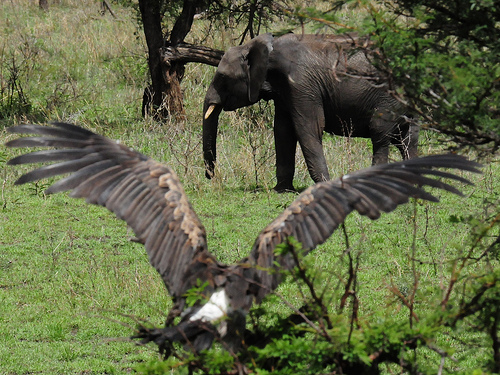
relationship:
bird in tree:
[8, 121, 485, 358] [129, 212, 499, 369]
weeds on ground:
[0, 0, 494, 375] [12, 75, 498, 344]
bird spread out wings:
[14, 47, 466, 365] [10, 101, 474, 311]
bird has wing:
[8, 121, 485, 358] [212, 159, 417, 252]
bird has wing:
[8, 121, 485, 358] [62, 127, 193, 278]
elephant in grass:
[196, 24, 430, 195] [7, 133, 494, 370]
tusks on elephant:
[200, 101, 218, 120] [196, 24, 430, 195]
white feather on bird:
[198, 291, 228, 326] [45, 145, 287, 345]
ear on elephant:
[248, 34, 272, 94] [196, 24, 430, 195]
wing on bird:
[250, 152, 483, 296] [8, 121, 485, 358]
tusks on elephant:
[200, 99, 217, 119] [198, 31, 442, 196]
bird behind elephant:
[8, 121, 485, 358] [196, 24, 430, 195]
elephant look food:
[196, 24, 430, 195] [89, 124, 268, 224]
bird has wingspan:
[8, 121, 485, 358] [1, 90, 492, 291]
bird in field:
[8, 121, 485, 358] [47, 53, 480, 265]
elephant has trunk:
[196, 18, 411, 193] [164, 73, 245, 185]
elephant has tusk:
[196, 18, 411, 193] [202, 104, 215, 121]